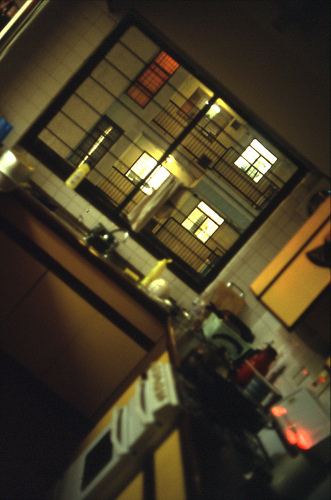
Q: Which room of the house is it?
A: It is a kitchen.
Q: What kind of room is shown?
A: It is a kitchen.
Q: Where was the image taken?
A: It was taken at the kitchen.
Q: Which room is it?
A: It is a kitchen.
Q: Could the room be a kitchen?
A: Yes, it is a kitchen.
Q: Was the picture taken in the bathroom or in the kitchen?
A: It was taken at the kitchen.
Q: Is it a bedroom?
A: No, it is a kitchen.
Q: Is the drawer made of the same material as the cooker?
A: No, the drawer is made of wood and the cooker is made of metal.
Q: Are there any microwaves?
A: No, there are no microwaves.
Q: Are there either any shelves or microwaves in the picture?
A: No, there are no microwaves or shelves.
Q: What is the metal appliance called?
A: The appliance is a cooker.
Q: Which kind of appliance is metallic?
A: The appliance is a cooker.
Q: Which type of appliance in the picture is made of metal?
A: The appliance is a cooker.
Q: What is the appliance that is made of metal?
A: The appliance is a cooker.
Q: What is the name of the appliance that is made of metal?
A: The appliance is a cooker.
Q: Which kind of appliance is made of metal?
A: The appliance is a cooker.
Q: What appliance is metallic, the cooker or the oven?
A: The cooker is metallic.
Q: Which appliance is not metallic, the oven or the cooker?
A: The oven is not metallic.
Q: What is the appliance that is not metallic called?
A: The appliance is an oven.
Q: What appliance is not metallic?
A: The appliance is an oven.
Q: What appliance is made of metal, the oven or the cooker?
A: The cooker is made of metal.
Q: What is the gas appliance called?
A: The appliance is a cooker.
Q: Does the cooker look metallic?
A: Yes, the cooker is metallic.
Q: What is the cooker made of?
A: The cooker is made of metal.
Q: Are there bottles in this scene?
A: Yes, there is a bottle.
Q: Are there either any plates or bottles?
A: Yes, there is a bottle.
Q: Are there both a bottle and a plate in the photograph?
A: No, there is a bottle but no plates.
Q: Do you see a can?
A: No, there are no cans.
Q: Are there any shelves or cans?
A: No, there are no cans or shelves.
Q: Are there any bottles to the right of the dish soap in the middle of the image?
A: Yes, there is a bottle to the right of the dish soap.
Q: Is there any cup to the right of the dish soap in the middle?
A: No, there is a bottle to the right of the dish soap.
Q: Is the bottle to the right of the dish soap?
A: Yes, the bottle is to the right of the dish soap.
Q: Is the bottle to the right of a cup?
A: No, the bottle is to the right of the dish soap.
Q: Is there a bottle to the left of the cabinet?
A: Yes, there is a bottle to the left of the cabinet.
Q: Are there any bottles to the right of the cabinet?
A: No, the bottle is to the left of the cabinet.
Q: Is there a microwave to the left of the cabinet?
A: No, there is a bottle to the left of the cabinet.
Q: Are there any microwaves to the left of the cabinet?
A: No, there is a bottle to the left of the cabinet.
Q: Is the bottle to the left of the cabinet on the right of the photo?
A: Yes, the bottle is to the left of the cabinet.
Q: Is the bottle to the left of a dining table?
A: No, the bottle is to the left of the cabinet.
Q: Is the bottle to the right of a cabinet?
A: No, the bottle is to the left of a cabinet.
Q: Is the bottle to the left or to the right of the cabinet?
A: The bottle is to the left of the cabinet.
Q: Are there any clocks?
A: No, there are no clocks.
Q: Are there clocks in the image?
A: No, there are no clocks.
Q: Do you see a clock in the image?
A: No, there are no clocks.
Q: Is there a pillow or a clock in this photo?
A: No, there are no clocks or pillows.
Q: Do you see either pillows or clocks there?
A: No, there are no clocks or pillows.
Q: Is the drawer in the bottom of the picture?
A: Yes, the drawer is in the bottom of the image.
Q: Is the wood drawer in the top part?
A: No, the drawer is in the bottom of the image.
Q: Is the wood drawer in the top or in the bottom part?
A: The drawer is in the bottom of the image.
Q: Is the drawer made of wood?
A: Yes, the drawer is made of wood.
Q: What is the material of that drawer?
A: The drawer is made of wood.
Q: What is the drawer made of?
A: The drawer is made of wood.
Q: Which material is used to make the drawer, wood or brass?
A: The drawer is made of wood.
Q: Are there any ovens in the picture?
A: Yes, there is an oven.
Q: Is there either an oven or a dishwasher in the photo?
A: Yes, there is an oven.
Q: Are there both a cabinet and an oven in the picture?
A: Yes, there are both an oven and a cabinet.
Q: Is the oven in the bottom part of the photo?
A: Yes, the oven is in the bottom of the image.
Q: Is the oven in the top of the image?
A: No, the oven is in the bottom of the image.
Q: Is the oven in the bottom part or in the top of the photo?
A: The oven is in the bottom of the image.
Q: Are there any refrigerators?
A: No, there are no refrigerators.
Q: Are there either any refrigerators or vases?
A: No, there are no refrigerators or vases.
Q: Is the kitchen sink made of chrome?
A: Yes, the sink is made of chrome.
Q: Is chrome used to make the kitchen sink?
A: Yes, the sink is made of chrome.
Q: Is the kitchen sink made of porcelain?
A: No, the sink is made of chrome.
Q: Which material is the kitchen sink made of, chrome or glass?
A: The sink is made of chrome.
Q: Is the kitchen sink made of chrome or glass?
A: The sink is made of chrome.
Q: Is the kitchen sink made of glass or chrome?
A: The sink is made of chrome.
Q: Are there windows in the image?
A: Yes, there is a window.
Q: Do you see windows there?
A: Yes, there is a window.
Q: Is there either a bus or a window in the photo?
A: Yes, there is a window.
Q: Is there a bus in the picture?
A: No, there are no buses.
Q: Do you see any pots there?
A: Yes, there is a pot.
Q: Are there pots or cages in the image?
A: Yes, there is a pot.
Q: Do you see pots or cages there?
A: Yes, there is a pot.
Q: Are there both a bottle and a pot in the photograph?
A: Yes, there are both a pot and a bottle.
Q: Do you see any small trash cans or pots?
A: Yes, there is a small pot.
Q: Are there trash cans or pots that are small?
A: Yes, the pot is small.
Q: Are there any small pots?
A: Yes, there is a small pot.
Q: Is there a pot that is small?
A: Yes, there is a pot that is small.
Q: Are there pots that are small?
A: Yes, there is a pot that is small.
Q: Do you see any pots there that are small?
A: Yes, there is a pot that is small.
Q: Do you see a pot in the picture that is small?
A: Yes, there is a pot that is small.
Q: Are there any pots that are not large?
A: Yes, there is a small pot.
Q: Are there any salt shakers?
A: No, there are no salt shakers.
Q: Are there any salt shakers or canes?
A: No, there are no salt shakers or canes.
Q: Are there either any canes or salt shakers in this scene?
A: No, there are no salt shakers or canes.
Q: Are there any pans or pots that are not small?
A: No, there is a pot but it is small.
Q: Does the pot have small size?
A: Yes, the pot is small.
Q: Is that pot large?
A: No, the pot is small.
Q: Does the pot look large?
A: No, the pot is small.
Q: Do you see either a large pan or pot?
A: No, there is a pot but it is small.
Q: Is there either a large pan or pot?
A: No, there is a pot but it is small.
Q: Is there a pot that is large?
A: No, there is a pot but it is small.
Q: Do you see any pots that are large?
A: No, there is a pot but it is small.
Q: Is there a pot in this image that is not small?
A: No, there is a pot but it is small.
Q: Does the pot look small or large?
A: The pot is small.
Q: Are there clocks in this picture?
A: No, there are no clocks.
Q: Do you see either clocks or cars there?
A: No, there are no clocks or cars.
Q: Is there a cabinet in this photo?
A: Yes, there is a cabinet.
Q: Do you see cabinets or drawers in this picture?
A: Yes, there is a cabinet.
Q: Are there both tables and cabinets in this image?
A: No, there is a cabinet but no tables.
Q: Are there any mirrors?
A: No, there are no mirrors.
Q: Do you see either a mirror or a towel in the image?
A: No, there are no mirrors or towels.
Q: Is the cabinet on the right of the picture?
A: Yes, the cabinet is on the right of the image.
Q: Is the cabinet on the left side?
A: No, the cabinet is on the right of the image.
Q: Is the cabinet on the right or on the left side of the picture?
A: The cabinet is on the right of the image.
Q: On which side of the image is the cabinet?
A: The cabinet is on the right of the image.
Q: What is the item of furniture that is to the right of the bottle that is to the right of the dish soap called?
A: The piece of furniture is a cabinet.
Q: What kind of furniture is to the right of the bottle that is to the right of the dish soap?
A: The piece of furniture is a cabinet.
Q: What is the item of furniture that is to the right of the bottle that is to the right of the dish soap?
A: The piece of furniture is a cabinet.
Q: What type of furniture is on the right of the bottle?
A: The piece of furniture is a cabinet.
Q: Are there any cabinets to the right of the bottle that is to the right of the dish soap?
A: Yes, there is a cabinet to the right of the bottle.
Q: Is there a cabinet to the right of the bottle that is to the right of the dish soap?
A: Yes, there is a cabinet to the right of the bottle.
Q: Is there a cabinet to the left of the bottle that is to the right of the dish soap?
A: No, the cabinet is to the right of the bottle.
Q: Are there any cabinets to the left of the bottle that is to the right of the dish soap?
A: No, the cabinet is to the right of the bottle.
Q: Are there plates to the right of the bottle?
A: No, there is a cabinet to the right of the bottle.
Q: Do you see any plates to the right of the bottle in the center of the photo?
A: No, there is a cabinet to the right of the bottle.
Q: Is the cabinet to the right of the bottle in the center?
A: Yes, the cabinet is to the right of the bottle.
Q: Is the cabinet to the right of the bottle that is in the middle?
A: Yes, the cabinet is to the right of the bottle.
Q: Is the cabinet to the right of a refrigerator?
A: No, the cabinet is to the right of the bottle.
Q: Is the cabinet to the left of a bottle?
A: No, the cabinet is to the right of a bottle.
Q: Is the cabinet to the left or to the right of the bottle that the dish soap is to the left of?
A: The cabinet is to the right of the bottle.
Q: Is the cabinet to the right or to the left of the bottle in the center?
A: The cabinet is to the right of the bottle.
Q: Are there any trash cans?
A: No, there are no trash cans.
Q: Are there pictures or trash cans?
A: No, there are no trash cans or pictures.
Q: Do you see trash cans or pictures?
A: No, there are no trash cans or pictures.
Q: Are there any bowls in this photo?
A: No, there are no bowls.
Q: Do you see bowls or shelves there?
A: No, there are no bowls or shelves.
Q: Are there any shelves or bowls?
A: No, there are no bowls or shelves.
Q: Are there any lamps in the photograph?
A: No, there are no lamps.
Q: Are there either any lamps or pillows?
A: No, there are no lamps or pillows.